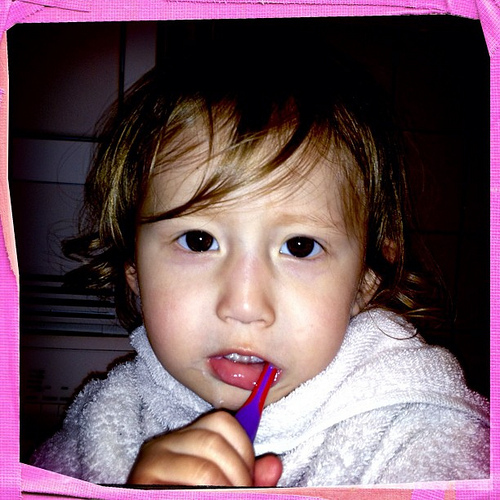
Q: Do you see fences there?
A: No, there are no fences.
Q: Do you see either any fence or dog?
A: No, there are no fences or dogs.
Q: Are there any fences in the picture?
A: No, there are no fences.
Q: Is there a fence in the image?
A: No, there are no fences.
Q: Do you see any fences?
A: No, there are no fences.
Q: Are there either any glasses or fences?
A: No, there are no fences or glasses.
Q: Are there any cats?
A: No, there are no cats.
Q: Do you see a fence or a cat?
A: No, there are no cats or fences.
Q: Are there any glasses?
A: No, there are no glasses.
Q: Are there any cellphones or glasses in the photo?
A: No, there are no glasses or cellphones.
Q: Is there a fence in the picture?
A: No, there are no fences.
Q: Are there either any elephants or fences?
A: No, there are no fences or elephants.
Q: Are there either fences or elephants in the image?
A: No, there are no fences or elephants.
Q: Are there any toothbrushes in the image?
A: Yes, there is a toothbrush.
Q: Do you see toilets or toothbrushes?
A: Yes, there is a toothbrush.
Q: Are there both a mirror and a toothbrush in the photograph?
A: No, there is a toothbrush but no mirrors.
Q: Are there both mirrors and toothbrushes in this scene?
A: No, there is a toothbrush but no mirrors.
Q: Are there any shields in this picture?
A: No, there are no shields.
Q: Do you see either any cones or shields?
A: No, there are no shields or cones.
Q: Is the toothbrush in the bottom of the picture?
A: Yes, the toothbrush is in the bottom of the image.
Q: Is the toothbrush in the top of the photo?
A: No, the toothbrush is in the bottom of the image.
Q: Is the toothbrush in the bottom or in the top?
A: The toothbrush is in the bottom of the image.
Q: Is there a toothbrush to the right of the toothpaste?
A: Yes, there is a toothbrush to the right of the toothpaste.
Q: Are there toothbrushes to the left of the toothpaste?
A: No, the toothbrush is to the right of the toothpaste.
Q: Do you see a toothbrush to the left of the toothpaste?
A: No, the toothbrush is to the right of the toothpaste.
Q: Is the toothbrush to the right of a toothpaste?
A: Yes, the toothbrush is to the right of a toothpaste.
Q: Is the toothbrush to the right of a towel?
A: No, the toothbrush is to the right of a toothpaste.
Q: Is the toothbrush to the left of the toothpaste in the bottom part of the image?
A: No, the toothbrush is to the right of the toothpaste.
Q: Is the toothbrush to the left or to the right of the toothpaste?
A: The toothbrush is to the right of the toothpaste.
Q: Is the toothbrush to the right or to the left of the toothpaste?
A: The toothbrush is to the right of the toothpaste.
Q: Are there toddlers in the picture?
A: Yes, there is a toddler.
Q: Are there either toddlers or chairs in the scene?
A: Yes, there is a toddler.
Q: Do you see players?
A: No, there are no players.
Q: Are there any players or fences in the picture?
A: No, there are no players or fences.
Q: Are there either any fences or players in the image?
A: No, there are no players or fences.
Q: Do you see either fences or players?
A: No, there are no players or fences.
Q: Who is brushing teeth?
A: The toddler is brushing teeth.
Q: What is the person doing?
A: The toddler is brushing teeth.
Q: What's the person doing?
A: The toddler is brushing teeth.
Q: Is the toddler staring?
A: Yes, the toddler is staring.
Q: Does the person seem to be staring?
A: Yes, the toddler is staring.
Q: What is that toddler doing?
A: The toddler is staring.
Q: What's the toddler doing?
A: The toddler is staring.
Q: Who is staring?
A: The toddler is staring.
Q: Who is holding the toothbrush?
A: The toddler is holding the toothbrush.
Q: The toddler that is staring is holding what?
A: The toddler is holding the toothbrush.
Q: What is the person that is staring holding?
A: The toddler is holding the toothbrush.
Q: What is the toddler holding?
A: The toddler is holding the toothbrush.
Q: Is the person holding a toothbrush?
A: Yes, the toddler is holding a toothbrush.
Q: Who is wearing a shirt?
A: The toddler is wearing a shirt.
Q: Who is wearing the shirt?
A: The toddler is wearing a shirt.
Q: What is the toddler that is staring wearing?
A: The toddler is wearing a shirt.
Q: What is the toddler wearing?
A: The toddler is wearing a shirt.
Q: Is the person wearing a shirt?
A: Yes, the toddler is wearing a shirt.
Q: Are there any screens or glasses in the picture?
A: No, there are no glasses or screens.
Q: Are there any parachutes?
A: No, there are no parachutes.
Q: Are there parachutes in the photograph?
A: No, there are no parachutes.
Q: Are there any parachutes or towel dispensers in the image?
A: No, there are no parachutes or towel dispensers.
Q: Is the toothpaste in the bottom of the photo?
A: Yes, the toothpaste is in the bottom of the image.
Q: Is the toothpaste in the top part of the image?
A: No, the toothpaste is in the bottom of the image.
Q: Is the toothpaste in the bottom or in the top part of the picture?
A: The toothpaste is in the bottom of the image.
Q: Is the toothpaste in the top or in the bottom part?
A: The toothpaste is in the bottom of the image.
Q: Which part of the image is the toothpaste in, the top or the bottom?
A: The toothpaste is in the bottom of the image.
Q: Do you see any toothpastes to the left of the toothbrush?
A: Yes, there is a toothpaste to the left of the toothbrush.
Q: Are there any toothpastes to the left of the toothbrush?
A: Yes, there is a toothpaste to the left of the toothbrush.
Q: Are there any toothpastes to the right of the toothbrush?
A: No, the toothpaste is to the left of the toothbrush.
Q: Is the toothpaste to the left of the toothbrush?
A: Yes, the toothpaste is to the left of the toothbrush.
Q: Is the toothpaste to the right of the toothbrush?
A: No, the toothpaste is to the left of the toothbrush.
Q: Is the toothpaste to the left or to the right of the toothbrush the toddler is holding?
A: The toothpaste is to the left of the toothbrush.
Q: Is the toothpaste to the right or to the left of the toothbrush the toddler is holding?
A: The toothpaste is to the left of the toothbrush.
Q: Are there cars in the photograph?
A: No, there are no cars.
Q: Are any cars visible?
A: No, there are no cars.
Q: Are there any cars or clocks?
A: No, there are no cars or clocks.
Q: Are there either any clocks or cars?
A: No, there are no cars or clocks.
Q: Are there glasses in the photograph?
A: No, there are no glasses.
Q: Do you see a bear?
A: No, there are no bears.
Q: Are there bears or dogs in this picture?
A: No, there are no bears or dogs.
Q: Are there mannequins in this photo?
A: No, there are no mannequins.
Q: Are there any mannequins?
A: No, there are no mannequins.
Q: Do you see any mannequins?
A: No, there are no mannequins.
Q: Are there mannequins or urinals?
A: No, there are no mannequins or urinals.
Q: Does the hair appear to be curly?
A: Yes, the hair is curly.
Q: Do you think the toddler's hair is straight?
A: No, the hair is curly.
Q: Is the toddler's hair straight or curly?
A: The hair is curly.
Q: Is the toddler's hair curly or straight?
A: The hair is curly.